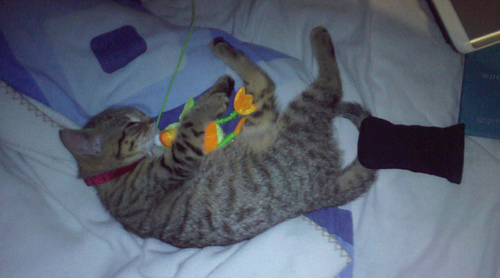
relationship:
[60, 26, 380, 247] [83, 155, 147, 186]
cat has a collar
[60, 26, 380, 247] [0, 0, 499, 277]
cat on bed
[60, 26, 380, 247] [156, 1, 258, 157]
cat hugging on a toy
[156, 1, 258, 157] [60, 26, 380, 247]
toy being hugged by cat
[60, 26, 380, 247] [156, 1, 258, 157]
cat playing with a toy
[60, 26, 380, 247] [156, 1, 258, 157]
cat holding toy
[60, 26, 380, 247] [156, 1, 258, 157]
cat hugging a toy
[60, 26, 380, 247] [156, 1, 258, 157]
cat holding on toy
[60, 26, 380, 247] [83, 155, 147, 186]
cat wearing a collar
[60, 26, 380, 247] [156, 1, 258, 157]
cat has a toy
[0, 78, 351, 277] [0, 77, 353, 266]
blanket has stitching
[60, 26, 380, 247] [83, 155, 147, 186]
cat has collar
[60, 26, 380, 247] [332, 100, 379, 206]
cat has a tail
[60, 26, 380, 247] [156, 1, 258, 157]
cat holding onto a toy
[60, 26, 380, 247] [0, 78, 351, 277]
cat on a blanket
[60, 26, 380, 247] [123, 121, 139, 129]
cat has an eye